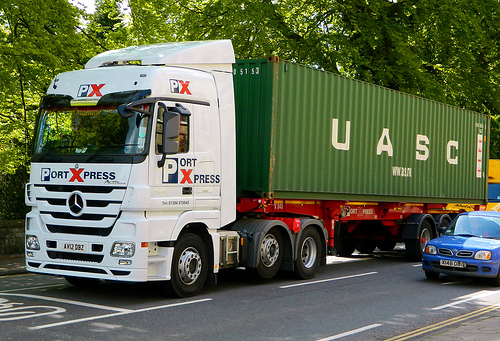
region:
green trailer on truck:
[222, 19, 493, 253]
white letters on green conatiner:
[295, 73, 493, 197]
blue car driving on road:
[374, 175, 495, 313]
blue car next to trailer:
[415, 192, 497, 282]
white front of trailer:
[7, 21, 265, 333]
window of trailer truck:
[32, 98, 156, 163]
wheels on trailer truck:
[162, 199, 359, 310]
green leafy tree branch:
[7, 2, 52, 112]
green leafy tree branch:
[327, 5, 411, 72]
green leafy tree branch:
[255, 8, 329, 59]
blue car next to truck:
[417, 185, 498, 298]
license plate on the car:
[430, 258, 474, 271]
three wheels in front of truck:
[137, 209, 336, 297]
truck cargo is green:
[246, 54, 498, 210]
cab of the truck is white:
[21, 38, 244, 289]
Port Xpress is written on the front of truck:
[34, 161, 123, 190]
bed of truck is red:
[243, 186, 470, 239]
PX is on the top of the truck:
[73, 74, 114, 101]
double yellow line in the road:
[415, 299, 497, 339]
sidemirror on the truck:
[156, 112, 192, 167]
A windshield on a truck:
[34, 100, 148, 155]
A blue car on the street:
[419, 210, 499, 281]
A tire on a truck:
[257, 223, 287, 277]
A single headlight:
[111, 239, 134, 255]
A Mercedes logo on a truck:
[67, 191, 86, 213]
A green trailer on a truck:
[232, 55, 488, 205]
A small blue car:
[422, 208, 498, 278]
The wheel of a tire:
[261, 234, 278, 266]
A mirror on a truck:
[162, 108, 179, 152]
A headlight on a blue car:
[424, 243, 438, 254]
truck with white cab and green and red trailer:
[20, 40, 493, 296]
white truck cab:
[22, 40, 239, 292]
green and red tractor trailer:
[232, 59, 492, 280]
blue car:
[423, 212, 498, 285]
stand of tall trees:
[0, 1, 499, 203]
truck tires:
[170, 215, 455, 295]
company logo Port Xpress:
[160, 155, 217, 183]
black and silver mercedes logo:
[66, 190, 83, 214]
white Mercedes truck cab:
[25, 40, 236, 293]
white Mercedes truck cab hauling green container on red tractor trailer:
[23, 39, 490, 279]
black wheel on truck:
[171, 221, 213, 296]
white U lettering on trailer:
[330, 110, 353, 153]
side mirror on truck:
[157, 100, 182, 171]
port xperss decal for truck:
[36, 165, 116, 182]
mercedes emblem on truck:
[60, 188, 86, 216]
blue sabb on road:
[420, 205, 496, 286]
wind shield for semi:
[30, 98, 151, 163]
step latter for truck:
[216, 230, 244, 270]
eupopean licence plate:
[56, 241, 86, 249]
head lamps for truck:
[109, 237, 136, 272]